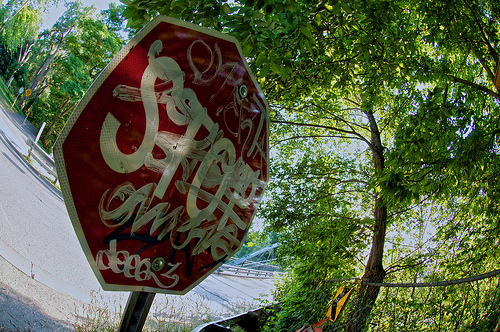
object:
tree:
[119, 0, 499, 331]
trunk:
[348, 262, 402, 331]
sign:
[324, 279, 358, 321]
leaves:
[297, 18, 317, 45]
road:
[0, 140, 337, 323]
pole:
[118, 289, 155, 331]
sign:
[79, 67, 281, 178]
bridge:
[220, 263, 287, 280]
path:
[0, 137, 287, 322]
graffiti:
[96, 38, 251, 287]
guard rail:
[233, 260, 278, 272]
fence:
[377, 277, 492, 331]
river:
[226, 263, 273, 274]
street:
[0, 137, 292, 322]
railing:
[213, 263, 297, 284]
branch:
[269, 118, 353, 136]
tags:
[235, 84, 248, 98]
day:
[30, 11, 169, 59]